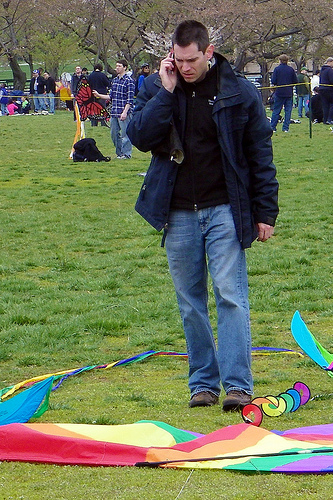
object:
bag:
[67, 134, 112, 163]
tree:
[0, 0, 37, 95]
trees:
[20, 23, 86, 84]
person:
[124, 18, 279, 413]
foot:
[187, 388, 218, 410]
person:
[69, 64, 85, 123]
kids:
[4, 97, 18, 119]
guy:
[124, 18, 280, 410]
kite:
[0, 309, 332, 477]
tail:
[241, 381, 311, 426]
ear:
[203, 41, 216, 64]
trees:
[298, 1, 332, 76]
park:
[0, 61, 332, 500]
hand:
[255, 221, 273, 246]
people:
[267, 53, 297, 135]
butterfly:
[72, 71, 110, 123]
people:
[40, 69, 56, 115]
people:
[89, 59, 135, 161]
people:
[318, 55, 332, 124]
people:
[29, 67, 49, 118]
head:
[168, 19, 216, 84]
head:
[277, 52, 288, 64]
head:
[113, 58, 126, 79]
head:
[73, 64, 82, 76]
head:
[140, 63, 150, 75]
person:
[86, 60, 111, 127]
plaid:
[107, 69, 135, 118]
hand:
[158, 51, 179, 95]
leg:
[160, 218, 221, 396]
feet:
[186, 386, 216, 408]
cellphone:
[168, 51, 177, 73]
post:
[306, 74, 312, 142]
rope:
[253, 80, 331, 94]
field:
[0, 60, 332, 499]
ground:
[0, 61, 332, 500]